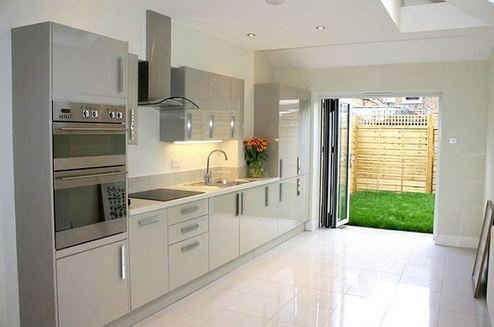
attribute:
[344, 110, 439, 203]
privacy fence — wood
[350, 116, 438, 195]
fence — wooden, tan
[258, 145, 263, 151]
flower — pink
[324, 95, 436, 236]
door — open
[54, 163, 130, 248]
stove — silver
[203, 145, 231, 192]
faucet — silver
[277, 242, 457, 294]
floor — white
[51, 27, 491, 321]
cabinets — silver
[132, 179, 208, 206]
stove — black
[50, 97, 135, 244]
stove — built-in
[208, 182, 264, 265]
cabinet — white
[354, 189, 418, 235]
grass — cut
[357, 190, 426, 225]
grass — green 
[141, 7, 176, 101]
overhead — silver